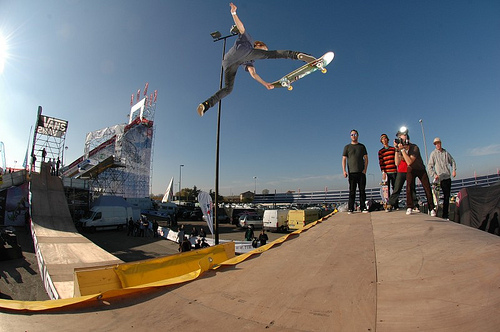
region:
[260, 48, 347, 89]
Skateboard in the air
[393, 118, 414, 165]
Man holding a camer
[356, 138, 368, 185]
Man's hand in pocket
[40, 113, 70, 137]
VANS sign is white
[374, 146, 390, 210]
Man holding a skate board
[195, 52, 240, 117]
Man's leg in air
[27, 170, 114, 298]
Ramp is long and wooden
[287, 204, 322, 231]
Yellow van is parked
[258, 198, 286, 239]
White van is parked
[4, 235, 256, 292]
Yellow tarp by ramp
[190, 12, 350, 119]
The skateboarder is in the air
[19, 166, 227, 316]
The ramp is made of wood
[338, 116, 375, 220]
Person standing at the top of the ramp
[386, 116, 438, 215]
Person holding a camera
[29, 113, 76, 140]
Black and white sign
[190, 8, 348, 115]
The skateboarder is holding onto the skateboard with one hand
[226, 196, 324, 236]
Cars parked behind the ramp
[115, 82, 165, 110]
Flags at the top of the ramp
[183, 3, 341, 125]
The skateboarder is wearing black pants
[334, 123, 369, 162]
The man is wearing sunglasses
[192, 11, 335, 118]
man in the air with a skateboard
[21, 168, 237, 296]
wooden skateboard ramp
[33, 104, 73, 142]
black and white "Vans" shoes sign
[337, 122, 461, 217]
5 teenage boys standing on wooden skateboard landing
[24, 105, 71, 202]
five people standing under the"Vans" sign at the top on a skateboard ramp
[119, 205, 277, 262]
people watching an event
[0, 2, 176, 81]
partial sun in blue sky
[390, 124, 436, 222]
someone taking a picture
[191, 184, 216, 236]
oval end flag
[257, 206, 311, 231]
two transport vans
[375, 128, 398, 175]
red and black striped shirt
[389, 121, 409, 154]
man holding a camera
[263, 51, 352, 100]
skateboard in the air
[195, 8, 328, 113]
man doing trick on skateboard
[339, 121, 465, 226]
four men standing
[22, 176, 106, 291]
wooden skateboarding rink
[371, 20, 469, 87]
clear blue cloudless sky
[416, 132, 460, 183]
man wearing grey shirt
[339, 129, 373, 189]
man wearing black shirt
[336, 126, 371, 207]
man wearing black pants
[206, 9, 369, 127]
skateboarder doing a trick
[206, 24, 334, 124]
skateboarder grabs the skateboard with one hand in the air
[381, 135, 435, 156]
man taking a picture of the trick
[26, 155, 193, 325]
wooden ramp for tricks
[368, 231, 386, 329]
nails in the wood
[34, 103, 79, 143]
VANS written on the banner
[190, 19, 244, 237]
lights behind the skateboarder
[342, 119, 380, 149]
man wearing sunglasses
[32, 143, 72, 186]
people standing on the side of ramp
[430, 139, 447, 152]
guy is wearing a ballcap